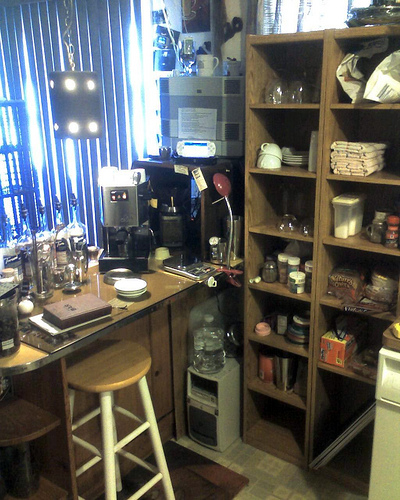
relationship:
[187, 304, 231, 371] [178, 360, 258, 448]
water bottle on top of pc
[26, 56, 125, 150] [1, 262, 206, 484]
lamp above desk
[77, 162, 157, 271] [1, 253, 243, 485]
machine on desk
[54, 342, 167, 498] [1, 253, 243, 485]
stool under desk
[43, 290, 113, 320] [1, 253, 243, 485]
book on desk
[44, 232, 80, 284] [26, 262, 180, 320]
bottle on counter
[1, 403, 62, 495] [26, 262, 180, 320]
shelf under counter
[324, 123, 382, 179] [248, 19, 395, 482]
towels on shelf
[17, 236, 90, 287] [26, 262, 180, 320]
bottles on counter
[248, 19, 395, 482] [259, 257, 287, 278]
shelf has spices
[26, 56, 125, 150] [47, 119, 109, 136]
lamp has holes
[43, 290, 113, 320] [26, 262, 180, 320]
book on counter